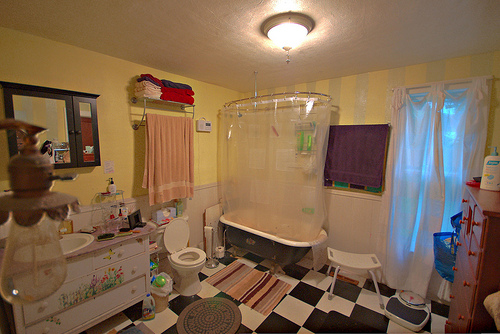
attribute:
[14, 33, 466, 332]
bathroom — big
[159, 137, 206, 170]
towel — wrinkle, white, shelf, purple, hanging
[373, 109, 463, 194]
window — blinds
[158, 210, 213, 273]
toilet — cover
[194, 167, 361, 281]
tub — bath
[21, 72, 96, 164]
mirror — reflection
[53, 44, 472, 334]
bathroom — big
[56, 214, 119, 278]
sink — bathroom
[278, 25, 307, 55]
light — clear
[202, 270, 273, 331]
rug — circle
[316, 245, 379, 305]
chair — white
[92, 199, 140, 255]
lotion — bottle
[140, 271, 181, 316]
trash — small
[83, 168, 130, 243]
bottle — cleaning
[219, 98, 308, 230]
curtain — shower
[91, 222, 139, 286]
counter — painted